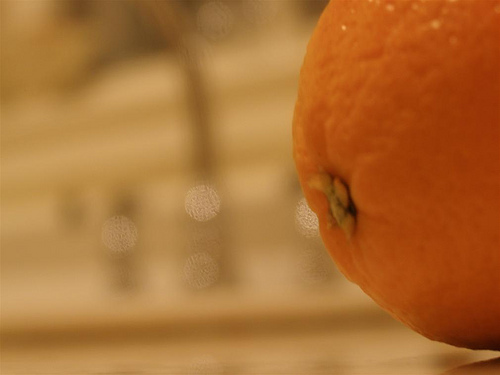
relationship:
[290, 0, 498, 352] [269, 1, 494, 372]
peel of fruit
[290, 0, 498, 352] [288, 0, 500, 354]
peel of fruit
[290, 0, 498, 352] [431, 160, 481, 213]
peel of orange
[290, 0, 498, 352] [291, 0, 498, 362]
peel of fruit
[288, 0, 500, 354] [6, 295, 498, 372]
fruit on a table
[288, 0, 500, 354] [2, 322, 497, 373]
fruit on table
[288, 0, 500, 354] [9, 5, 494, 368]
fruit in kitchen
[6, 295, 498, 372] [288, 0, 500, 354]
table with fruit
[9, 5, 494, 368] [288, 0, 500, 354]
kitchen with fruit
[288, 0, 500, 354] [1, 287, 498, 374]
fruit sitting on a counter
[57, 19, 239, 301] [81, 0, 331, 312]
faucet of sink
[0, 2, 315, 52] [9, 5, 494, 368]
window in kitchen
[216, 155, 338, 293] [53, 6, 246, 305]
lever of faucet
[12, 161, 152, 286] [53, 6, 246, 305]
lever of faucet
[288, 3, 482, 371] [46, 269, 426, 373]
fruit on counter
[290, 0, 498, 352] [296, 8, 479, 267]
peel on fruit